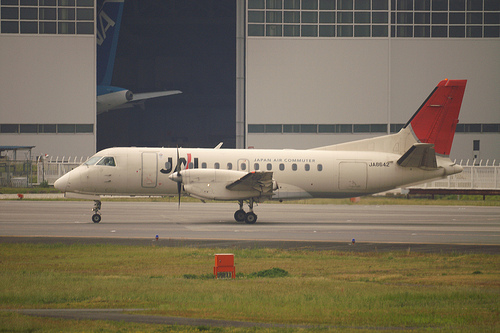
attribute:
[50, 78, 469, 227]
plane — ready for takeoff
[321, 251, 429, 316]
grass — green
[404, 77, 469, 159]
tail — orange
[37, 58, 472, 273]
plane — doing preflight checks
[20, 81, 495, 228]
plane — half full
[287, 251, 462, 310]
grass — green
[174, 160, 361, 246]
wing — short back